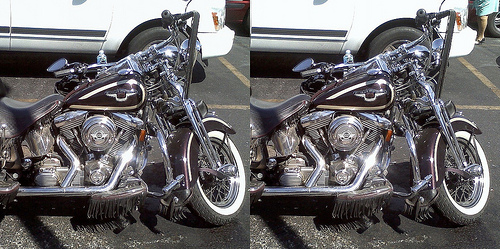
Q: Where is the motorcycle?
A: A parking lot.